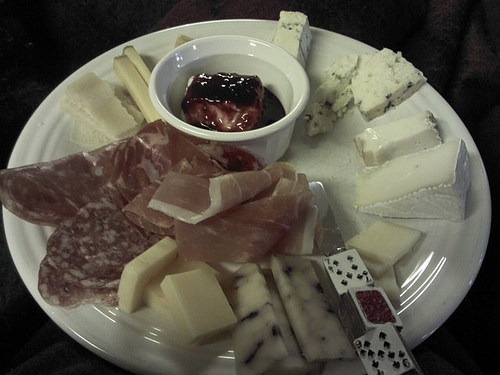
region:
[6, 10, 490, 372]
plate holding cheese and meats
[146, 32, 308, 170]
dipping sauce on plate with meat and cheese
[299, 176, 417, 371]
knife to spread cheese with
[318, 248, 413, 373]
handle of cheese knife is made in design of playing cards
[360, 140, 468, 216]
brie cheese on cheese plate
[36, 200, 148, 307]
slices of salami next to cheddar cheese on plate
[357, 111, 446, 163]
brie cheese next to blue cheese on cheese plate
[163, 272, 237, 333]
cheddar cheese squared on cheese plate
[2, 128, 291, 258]
various styles of sliced meats to partner with the cheese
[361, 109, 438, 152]
small piece of brie cheese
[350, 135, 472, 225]
white cheese wedge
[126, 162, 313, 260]
thin sliced meat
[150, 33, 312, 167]
white ceramic bowl with purple sauce over cheese morsel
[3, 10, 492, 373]
round white plate with cheese wedge samples and thin meats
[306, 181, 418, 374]
knife spreader with game card handle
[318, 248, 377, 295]
seven of clubs design on knife handle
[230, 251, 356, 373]
yellow and black cheese slices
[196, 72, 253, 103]
purple sauce on cheese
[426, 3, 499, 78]
black material tablecloth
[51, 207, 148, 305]
spotted thinly slices meat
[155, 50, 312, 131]
Barbeque sauce?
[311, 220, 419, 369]
Is this food or playing cards?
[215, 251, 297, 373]
Is that mold on the cheese?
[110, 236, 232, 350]
Some type of white cheese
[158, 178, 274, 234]
Some type of meat. Ham maybe?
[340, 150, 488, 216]
Is this cheese or desert?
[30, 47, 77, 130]
White plate on some type of black background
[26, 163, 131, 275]
What type of meat is that?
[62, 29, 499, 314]
This plate is not appetizing at all!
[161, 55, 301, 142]
sauce in a bowl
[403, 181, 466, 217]
edge of a cake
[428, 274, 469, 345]
edge of a plate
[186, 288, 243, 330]
part of a cake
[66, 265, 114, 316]
part of a meat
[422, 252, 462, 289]
part of a plate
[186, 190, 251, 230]
part of a ham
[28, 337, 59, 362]
part of a cloth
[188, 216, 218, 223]
edge of a plate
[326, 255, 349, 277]
part of some cards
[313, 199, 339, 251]
part of a blade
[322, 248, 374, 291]
Seven of spades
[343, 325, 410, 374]
9 of spades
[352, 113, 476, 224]
brie cheese on right side of plate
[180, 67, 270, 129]
something covered in jelly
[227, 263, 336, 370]
cheese with dark purple colors on the bottom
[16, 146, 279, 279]
different meats on the left of plate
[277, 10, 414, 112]
blue cheese in upper right area of plate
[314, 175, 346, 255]
top of knife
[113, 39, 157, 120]
narrow pieces of cheese with dark edges shown at top left of plate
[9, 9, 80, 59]
black background in top left